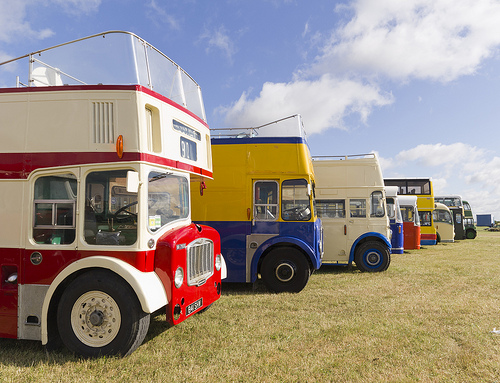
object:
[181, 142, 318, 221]
yellow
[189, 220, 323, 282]
blue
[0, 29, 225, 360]
buses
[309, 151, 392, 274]
buses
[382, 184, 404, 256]
buses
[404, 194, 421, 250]
buses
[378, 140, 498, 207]
clouds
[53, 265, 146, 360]
wheel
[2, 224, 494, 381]
lawn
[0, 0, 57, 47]
clouds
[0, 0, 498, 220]
sky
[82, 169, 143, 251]
window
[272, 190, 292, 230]
edge bus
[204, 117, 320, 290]
rv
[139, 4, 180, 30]
clouds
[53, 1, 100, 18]
clouds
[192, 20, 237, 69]
clouds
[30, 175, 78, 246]
window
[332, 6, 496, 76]
clouds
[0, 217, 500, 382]
field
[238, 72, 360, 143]
clouds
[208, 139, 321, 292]
front